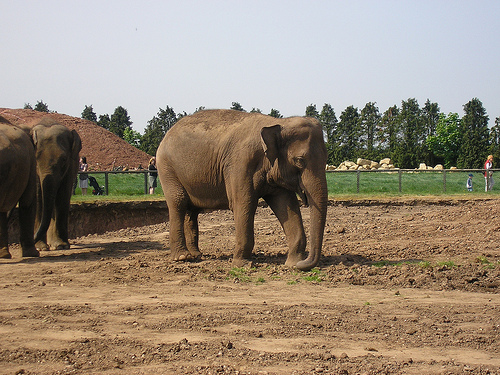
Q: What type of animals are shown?
A: Elephants.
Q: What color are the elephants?
A: Brown.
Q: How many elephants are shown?
A: Three.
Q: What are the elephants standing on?
A: Dirt.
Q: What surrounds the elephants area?
A: Fence.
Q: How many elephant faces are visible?
A: Two.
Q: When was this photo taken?
A: Daytime.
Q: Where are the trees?
A: Background.